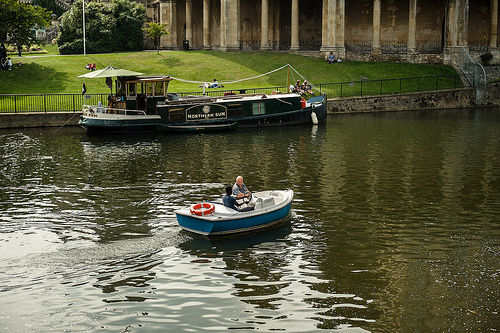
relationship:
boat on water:
[176, 188, 293, 237] [2, 104, 499, 332]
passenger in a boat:
[233, 175, 248, 198] [176, 188, 293, 237]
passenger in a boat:
[222, 186, 250, 211] [176, 188, 293, 237]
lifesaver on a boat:
[189, 203, 213, 217] [176, 188, 293, 237]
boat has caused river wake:
[176, 188, 293, 237] [4, 184, 328, 327]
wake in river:
[4, 184, 328, 327] [2, 104, 499, 332]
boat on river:
[78, 64, 328, 132] [2, 104, 499, 332]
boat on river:
[176, 188, 293, 237] [2, 104, 499, 332]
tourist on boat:
[233, 175, 248, 198] [176, 188, 293, 237]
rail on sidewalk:
[0, 72, 474, 113] [0, 86, 475, 134]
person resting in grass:
[328, 52, 337, 63] [0, 48, 462, 114]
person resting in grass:
[199, 78, 216, 89] [0, 48, 462, 114]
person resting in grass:
[85, 63, 96, 69] [0, 48, 462, 114]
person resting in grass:
[4, 57, 11, 69] [0, 48, 462, 114]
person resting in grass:
[300, 81, 315, 95] [0, 48, 462, 114]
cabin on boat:
[114, 74, 173, 114] [78, 64, 328, 132]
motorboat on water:
[176, 188, 293, 237] [2, 104, 499, 332]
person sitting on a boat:
[233, 175, 248, 198] [176, 188, 293, 237]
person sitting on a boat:
[222, 186, 250, 211] [176, 188, 293, 237]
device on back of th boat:
[189, 203, 213, 217] [176, 188, 293, 237]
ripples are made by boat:
[4, 184, 328, 327] [176, 188, 293, 237]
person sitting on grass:
[328, 52, 337, 63] [0, 48, 462, 114]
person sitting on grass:
[199, 78, 216, 89] [0, 48, 462, 114]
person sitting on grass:
[85, 63, 96, 69] [0, 48, 462, 114]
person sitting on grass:
[4, 57, 11, 69] [0, 48, 462, 114]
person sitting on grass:
[300, 81, 315, 95] [0, 48, 462, 114]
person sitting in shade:
[4, 57, 11, 69] [2, 62, 69, 101]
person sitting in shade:
[328, 52, 337, 63] [196, 50, 467, 94]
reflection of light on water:
[0, 131, 372, 332] [2, 104, 499, 332]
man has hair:
[233, 175, 248, 198] [236, 175, 244, 181]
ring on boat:
[189, 203, 213, 217] [176, 188, 293, 237]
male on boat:
[233, 175, 248, 198] [176, 188, 293, 237]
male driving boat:
[222, 186, 250, 211] [176, 188, 293, 237]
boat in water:
[78, 64, 328, 132] [2, 104, 499, 332]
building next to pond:
[141, 2, 499, 64] [2, 104, 499, 332]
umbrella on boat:
[78, 65, 145, 77] [78, 64, 328, 132]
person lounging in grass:
[300, 81, 315, 95] [0, 48, 462, 114]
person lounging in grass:
[85, 63, 96, 69] [0, 48, 462, 114]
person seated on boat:
[233, 175, 248, 198] [176, 188, 293, 237]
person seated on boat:
[222, 186, 250, 211] [176, 188, 293, 237]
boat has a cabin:
[78, 64, 328, 132] [114, 74, 173, 114]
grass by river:
[0, 48, 462, 114] [2, 104, 499, 332]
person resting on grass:
[4, 57, 11, 69] [0, 48, 462, 114]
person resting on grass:
[85, 63, 96, 69] [0, 48, 462, 114]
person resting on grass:
[199, 78, 216, 89] [0, 48, 462, 114]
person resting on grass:
[328, 52, 337, 63] [0, 48, 462, 114]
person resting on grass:
[300, 81, 315, 95] [0, 48, 462, 114]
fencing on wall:
[0, 72, 474, 113] [0, 86, 475, 134]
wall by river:
[0, 86, 475, 134] [2, 104, 499, 332]